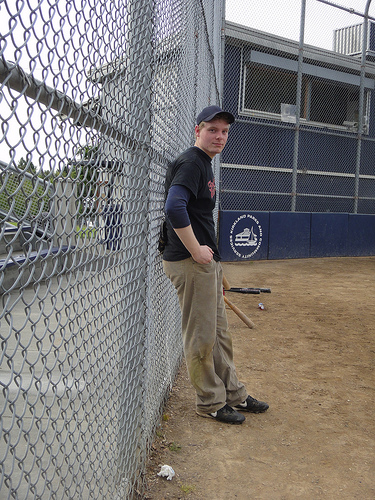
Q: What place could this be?
A: It is a field.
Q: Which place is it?
A: It is a field.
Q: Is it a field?
A: Yes, it is a field.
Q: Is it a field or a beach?
A: It is a field.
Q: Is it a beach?
A: No, it is a field.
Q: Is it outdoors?
A: Yes, it is outdoors.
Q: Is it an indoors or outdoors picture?
A: It is outdoors.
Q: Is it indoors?
A: No, it is outdoors.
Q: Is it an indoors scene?
A: No, it is outdoors.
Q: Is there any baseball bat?
A: Yes, there is a baseball bat.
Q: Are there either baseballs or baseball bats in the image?
A: Yes, there is a baseball bat.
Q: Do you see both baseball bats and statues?
A: No, there is a baseball bat but no statues.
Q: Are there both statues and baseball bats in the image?
A: No, there is a baseball bat but no statues.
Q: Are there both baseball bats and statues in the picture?
A: No, there is a baseball bat but no statues.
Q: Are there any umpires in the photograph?
A: No, there are no umpires.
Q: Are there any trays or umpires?
A: No, there are no umpires or trays.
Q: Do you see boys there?
A: No, there are no boys.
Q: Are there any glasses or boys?
A: No, there are no boys or glasses.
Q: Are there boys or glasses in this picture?
A: No, there are no boys or glasses.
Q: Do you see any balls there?
A: No, there are no balls.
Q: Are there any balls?
A: No, there are no balls.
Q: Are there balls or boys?
A: No, there are no balls or boys.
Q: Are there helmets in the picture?
A: No, there are no helmets.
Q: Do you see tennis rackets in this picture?
A: No, there are no tennis rackets.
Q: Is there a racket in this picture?
A: No, there are no rackets.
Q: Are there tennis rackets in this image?
A: No, there are no tennis rackets.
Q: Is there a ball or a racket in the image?
A: No, there are no rackets or balls.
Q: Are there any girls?
A: No, there are no girls.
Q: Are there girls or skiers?
A: No, there are no girls or skiers.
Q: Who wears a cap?
A: The man wears a cap.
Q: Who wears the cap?
A: The man wears a cap.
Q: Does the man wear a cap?
A: Yes, the man wears a cap.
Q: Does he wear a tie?
A: No, the man wears a cap.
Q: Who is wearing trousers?
A: The man is wearing trousers.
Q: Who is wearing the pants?
A: The man is wearing trousers.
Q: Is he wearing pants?
A: Yes, the man is wearing pants.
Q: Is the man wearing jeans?
A: No, the man is wearing pants.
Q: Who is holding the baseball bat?
A: The man is holding the baseball bat.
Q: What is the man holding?
A: The man is holding the baseball bat.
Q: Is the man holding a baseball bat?
A: Yes, the man is holding a baseball bat.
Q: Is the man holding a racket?
A: No, the man is holding a baseball bat.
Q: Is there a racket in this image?
A: No, there are no rackets.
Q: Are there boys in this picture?
A: No, there are no boys.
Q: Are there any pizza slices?
A: No, there are no pizza slices.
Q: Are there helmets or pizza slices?
A: No, there are no pizza slices or helmets.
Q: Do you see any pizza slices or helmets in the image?
A: No, there are no pizza slices or helmets.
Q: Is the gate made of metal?
A: Yes, the gate is made of metal.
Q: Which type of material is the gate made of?
A: The gate is made of metal.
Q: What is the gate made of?
A: The gate is made of metal.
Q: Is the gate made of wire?
A: No, the gate is made of metal.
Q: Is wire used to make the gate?
A: No, the gate is made of metal.